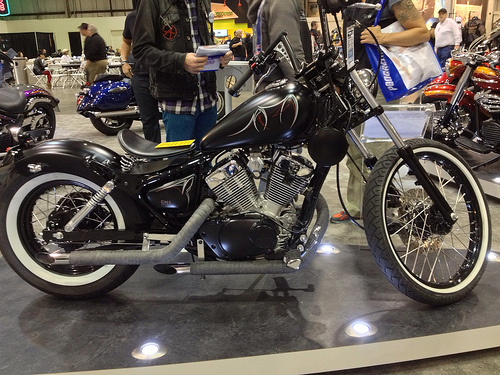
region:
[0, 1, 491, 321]
all black motercycle with chrome motor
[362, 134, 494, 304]
front motocycle tire with whitewall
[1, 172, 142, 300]
back whitewall motorcycle tire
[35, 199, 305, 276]
chrome exhauste pipes on bike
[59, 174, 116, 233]
shock absorbers on back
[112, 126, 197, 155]
black seat on black bike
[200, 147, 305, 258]
motor on black motorcycle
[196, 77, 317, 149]
gas tank on motorcycle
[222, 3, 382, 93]
handle bars on black bike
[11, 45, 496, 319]
motorized bike on display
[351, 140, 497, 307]
front tire on bike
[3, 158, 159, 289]
rear tire of bike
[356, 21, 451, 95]
bag on person's shoulder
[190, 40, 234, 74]
info in person's hand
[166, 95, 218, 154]
pants on the person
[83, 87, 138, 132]
rear tire on bike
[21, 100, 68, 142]
rear tire on bike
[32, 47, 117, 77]
tables and chairs in back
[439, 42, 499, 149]
other motorbikes on display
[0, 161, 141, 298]
rear wheel of motorcycle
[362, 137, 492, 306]
front wheel of motorcycle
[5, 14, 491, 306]
parked black motorcycle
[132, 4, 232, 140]
man holding papers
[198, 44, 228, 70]
stack of papers being held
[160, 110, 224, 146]
blue jeans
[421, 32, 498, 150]
red and orange motorcycle in the background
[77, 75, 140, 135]
back half of a blue motorcycle in the background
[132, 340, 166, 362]
reflection of light on the floor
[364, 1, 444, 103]
blue and white bag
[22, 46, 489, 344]
a motorocycle on display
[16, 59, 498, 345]
a motorocycle on display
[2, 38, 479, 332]
a motorocycle on display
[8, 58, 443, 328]
a motorocycle on display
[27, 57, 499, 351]
a motorocycle on display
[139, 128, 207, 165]
the tag is yellow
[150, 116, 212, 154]
the tag is yellow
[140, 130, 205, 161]
the tag is yellow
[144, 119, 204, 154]
the tag is yellow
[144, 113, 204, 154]
the tag is yellow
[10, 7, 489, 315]
motorcycle is color black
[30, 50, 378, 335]
A black motorcycle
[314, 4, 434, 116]
A man with tattoos on his arm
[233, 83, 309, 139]
Red and white pinstripes on the gas tank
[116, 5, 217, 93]
A person with a leather jacket on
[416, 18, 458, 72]
A man in white shirt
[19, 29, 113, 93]
People setting at a table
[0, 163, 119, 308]
Motorcycle wheel with white stripe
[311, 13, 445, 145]
A white and blue shoulder bag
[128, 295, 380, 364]
Lights on the floor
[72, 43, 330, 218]
A black motorcycle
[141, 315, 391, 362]
Lights on and on the ground